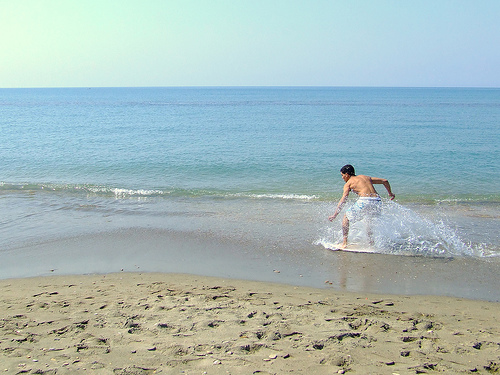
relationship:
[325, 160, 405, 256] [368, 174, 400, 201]
man has right arm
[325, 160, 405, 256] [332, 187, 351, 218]
man has extended arms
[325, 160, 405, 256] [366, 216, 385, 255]
man has right leg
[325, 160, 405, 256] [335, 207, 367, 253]
man has left leg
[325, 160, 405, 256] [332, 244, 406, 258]
man on surfboard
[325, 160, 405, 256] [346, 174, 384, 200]
man has strong back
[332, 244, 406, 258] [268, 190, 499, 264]
surfboard in water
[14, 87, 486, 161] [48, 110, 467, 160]
ocean has no swimmers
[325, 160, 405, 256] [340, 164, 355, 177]
man has brown hair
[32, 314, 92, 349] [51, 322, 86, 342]
sand has a footprint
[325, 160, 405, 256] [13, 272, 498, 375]
surfer on beach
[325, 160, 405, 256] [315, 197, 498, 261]
surfer formed a splash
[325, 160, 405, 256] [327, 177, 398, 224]
boy has extended arms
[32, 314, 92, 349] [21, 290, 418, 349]
sand has footprints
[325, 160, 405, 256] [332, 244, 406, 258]
man on a surfboard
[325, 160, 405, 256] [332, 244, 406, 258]
man splashing with surfboard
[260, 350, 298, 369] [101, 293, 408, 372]
rocks are in sand